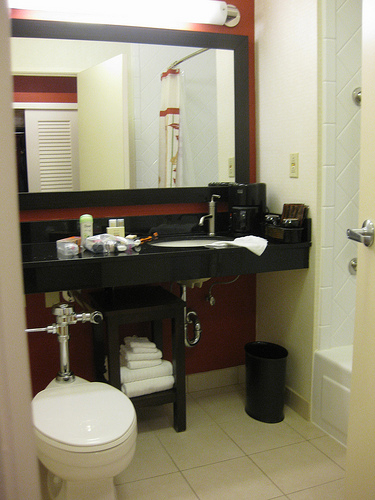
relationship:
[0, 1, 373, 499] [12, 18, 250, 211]
bathroom with mirror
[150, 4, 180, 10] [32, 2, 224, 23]
oblong light with cover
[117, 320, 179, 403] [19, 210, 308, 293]
shelf under countertop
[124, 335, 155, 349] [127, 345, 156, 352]
towel on towel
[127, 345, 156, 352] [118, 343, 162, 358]
towel on towel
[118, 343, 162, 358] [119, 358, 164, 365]
towel on towel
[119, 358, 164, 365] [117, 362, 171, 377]
towel on towel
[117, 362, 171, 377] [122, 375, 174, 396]
towel on towel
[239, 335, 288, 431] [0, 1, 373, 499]
trash bin in bathroom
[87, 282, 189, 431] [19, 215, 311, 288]
stool under counter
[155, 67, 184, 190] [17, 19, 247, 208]
reflection in bathroom mirror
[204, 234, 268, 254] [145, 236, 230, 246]
towel over sink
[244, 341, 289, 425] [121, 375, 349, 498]
trash bin on floor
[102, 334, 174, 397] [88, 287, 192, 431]
towels on shelf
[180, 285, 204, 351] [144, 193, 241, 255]
pipe under sink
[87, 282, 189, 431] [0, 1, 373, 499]
stool in bathroom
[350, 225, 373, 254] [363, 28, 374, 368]
silver handle on door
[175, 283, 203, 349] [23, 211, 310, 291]
pipe under counter